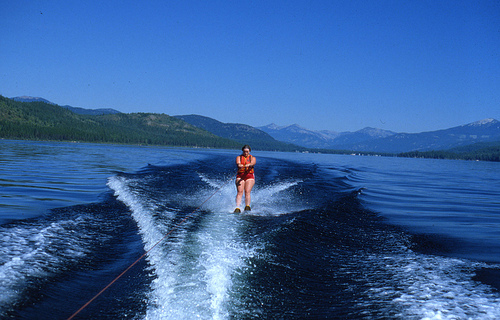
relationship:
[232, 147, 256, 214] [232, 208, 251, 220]
woman water skiing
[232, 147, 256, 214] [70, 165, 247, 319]
woman holding rope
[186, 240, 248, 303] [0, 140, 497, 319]
water shimmering in lake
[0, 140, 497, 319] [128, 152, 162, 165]
lake deep blue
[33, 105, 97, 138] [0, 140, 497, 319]
hill near lake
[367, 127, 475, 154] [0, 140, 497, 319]
mountains are near lake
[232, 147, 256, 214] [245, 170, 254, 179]
woman wearing red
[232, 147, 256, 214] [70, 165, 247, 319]
woman dragged by rope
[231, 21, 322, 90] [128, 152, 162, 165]
sky clear and blue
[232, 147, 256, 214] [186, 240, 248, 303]
woman on water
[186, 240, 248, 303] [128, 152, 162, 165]
water calm and blue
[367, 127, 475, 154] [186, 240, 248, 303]
mountains are near water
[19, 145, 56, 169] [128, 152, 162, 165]
lake large and blue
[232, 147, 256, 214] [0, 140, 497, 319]
woman alone in lake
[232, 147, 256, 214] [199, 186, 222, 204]
woman holding onto a rope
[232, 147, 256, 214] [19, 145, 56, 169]
woman waterskiing on lake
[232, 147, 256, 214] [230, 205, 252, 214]
woman uses waterskiis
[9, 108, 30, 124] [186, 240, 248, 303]
green mountains near water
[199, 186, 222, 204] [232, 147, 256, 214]
rope attached to woman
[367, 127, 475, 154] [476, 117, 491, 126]
mountains with snow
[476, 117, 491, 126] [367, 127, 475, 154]
snow on mountains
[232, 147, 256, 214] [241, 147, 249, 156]
woman wearing sunglasses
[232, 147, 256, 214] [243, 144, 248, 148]
woman has brown hair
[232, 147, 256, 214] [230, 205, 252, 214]
woman on waterskiis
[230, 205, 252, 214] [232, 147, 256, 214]
skiis on woman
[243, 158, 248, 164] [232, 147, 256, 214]
orange vest on woman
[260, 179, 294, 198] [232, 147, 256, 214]
white waves behind woman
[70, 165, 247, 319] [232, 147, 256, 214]
rope attached to woman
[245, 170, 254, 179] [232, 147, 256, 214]
red shorts on woman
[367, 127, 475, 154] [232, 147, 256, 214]
mountains behind woman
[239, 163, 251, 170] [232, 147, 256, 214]
hands of woman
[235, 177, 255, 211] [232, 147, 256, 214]
legs on woman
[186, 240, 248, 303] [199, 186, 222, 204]
water skier holding rope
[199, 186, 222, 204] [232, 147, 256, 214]
rope pulling woman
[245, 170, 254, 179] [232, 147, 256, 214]
red swimsuit on woman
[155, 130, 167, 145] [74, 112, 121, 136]
tree covered hilside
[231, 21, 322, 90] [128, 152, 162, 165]
sky beautiful and blue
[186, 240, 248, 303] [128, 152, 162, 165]
water deep and blue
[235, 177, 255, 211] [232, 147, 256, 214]
legs of woman